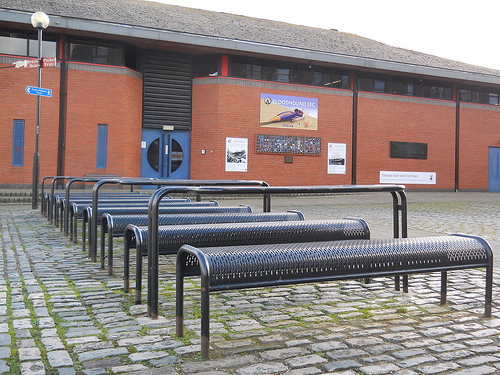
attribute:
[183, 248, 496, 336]
bench — metal, black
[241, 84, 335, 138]
sign — multicolored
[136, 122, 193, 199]
door — blue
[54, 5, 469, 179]
building — brick, large, tall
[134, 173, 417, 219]
bar — black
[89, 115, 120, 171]
window — blue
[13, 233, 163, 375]
ground — cobblestone, brick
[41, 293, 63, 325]
grass — growing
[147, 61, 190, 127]
wall — black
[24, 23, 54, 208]
pole — black, metal, tall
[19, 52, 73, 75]
sign — red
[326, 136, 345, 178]
sign — white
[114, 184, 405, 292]
metal — black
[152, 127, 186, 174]
windows — semi-circular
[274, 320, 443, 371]
stones — gray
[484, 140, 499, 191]
shape — blue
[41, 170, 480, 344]
lot — brick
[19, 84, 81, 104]
sign — blue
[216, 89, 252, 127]
brick — red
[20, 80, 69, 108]
street sign — blue